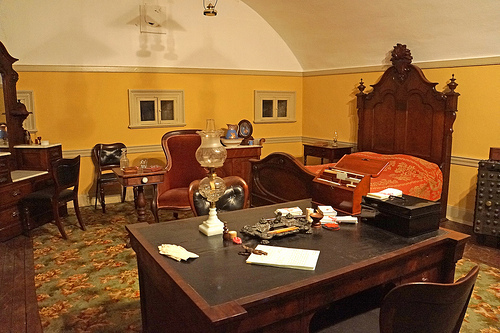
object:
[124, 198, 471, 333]
desk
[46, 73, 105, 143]
wall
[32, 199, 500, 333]
carpet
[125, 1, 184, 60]
shadow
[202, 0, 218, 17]
ceiling lantern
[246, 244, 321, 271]
papers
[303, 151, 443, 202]
bedspread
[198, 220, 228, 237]
base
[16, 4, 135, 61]
wall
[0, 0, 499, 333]
bedroom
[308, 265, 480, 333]
chair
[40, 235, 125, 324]
floor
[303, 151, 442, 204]
blanket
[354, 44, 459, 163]
headboard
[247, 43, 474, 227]
bed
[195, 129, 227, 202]
colorless glass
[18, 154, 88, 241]
chair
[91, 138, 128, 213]
chair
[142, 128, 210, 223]
chair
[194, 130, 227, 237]
lamp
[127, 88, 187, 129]
white frame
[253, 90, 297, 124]
white frame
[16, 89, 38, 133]
white frame